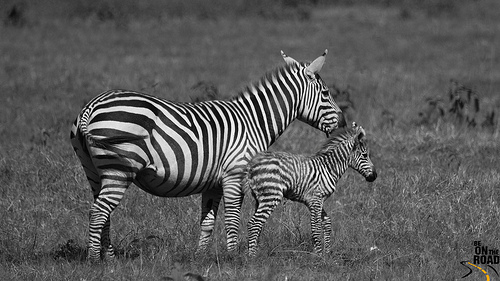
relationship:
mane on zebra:
[320, 128, 354, 154] [240, 123, 375, 257]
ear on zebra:
[350, 122, 370, 145] [254, 124, 383, 260]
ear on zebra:
[278, 49, 297, 70] [67, 42, 349, 272]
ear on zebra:
[300, 47, 335, 72] [67, 42, 349, 272]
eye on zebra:
[321, 90, 330, 96] [67, 42, 349, 272]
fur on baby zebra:
[318, 124, 359, 161] [236, 118, 378, 262]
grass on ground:
[408, 128, 470, 277] [384, 49, 474, 256]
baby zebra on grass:
[236, 121, 379, 262] [3, 0, 499, 280]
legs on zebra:
[90, 166, 247, 262] [80, 39, 320, 234]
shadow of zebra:
[40, 236, 140, 266] [67, 42, 349, 272]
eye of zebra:
[321, 90, 330, 96] [67, 42, 349, 272]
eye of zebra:
[360, 146, 367, 162] [240, 123, 375, 257]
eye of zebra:
[314, 90, 331, 99] [53, 49, 391, 264]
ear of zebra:
[279, 49, 297, 70] [67, 42, 349, 272]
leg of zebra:
[86, 166, 124, 261] [64, 46, 340, 250]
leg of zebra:
[224, 164, 245, 263] [67, 42, 349, 272]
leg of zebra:
[247, 182, 279, 263] [58, 31, 420, 251]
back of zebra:
[114, 94, 254, 138] [16, 30, 415, 277]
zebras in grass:
[64, 49, 383, 257] [377, 68, 490, 258]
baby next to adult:
[238, 117, 381, 263] [66, 44, 347, 266]